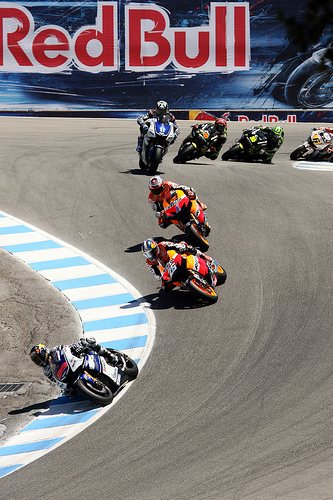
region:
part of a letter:
[207, 22, 226, 64]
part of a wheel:
[88, 388, 104, 403]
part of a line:
[58, 429, 94, 464]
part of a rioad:
[250, 391, 284, 432]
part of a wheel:
[85, 387, 115, 420]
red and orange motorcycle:
[157, 250, 226, 301]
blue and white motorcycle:
[50, 345, 133, 403]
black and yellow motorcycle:
[222, 130, 280, 165]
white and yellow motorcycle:
[290, 125, 331, 163]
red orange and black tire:
[189, 278, 219, 302]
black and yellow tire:
[27, 344, 43, 363]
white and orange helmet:
[147, 174, 158, 184]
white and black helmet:
[153, 97, 164, 105]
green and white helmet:
[269, 123, 277, 131]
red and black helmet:
[213, 116, 224, 124]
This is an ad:
[7, 31, 241, 124]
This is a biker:
[136, 228, 238, 296]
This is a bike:
[193, 253, 238, 348]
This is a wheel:
[71, 369, 132, 423]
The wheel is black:
[64, 364, 140, 437]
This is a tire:
[78, 394, 114, 406]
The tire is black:
[39, 378, 153, 426]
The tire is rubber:
[86, 381, 110, 417]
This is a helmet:
[133, 219, 172, 284]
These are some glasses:
[129, 250, 149, 258]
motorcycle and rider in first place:
[26, 331, 139, 402]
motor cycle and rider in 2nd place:
[129, 231, 227, 310]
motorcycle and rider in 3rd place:
[146, 172, 212, 249]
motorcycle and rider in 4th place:
[132, 99, 180, 171]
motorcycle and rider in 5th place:
[171, 115, 229, 165]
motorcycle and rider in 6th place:
[219, 125, 284, 164]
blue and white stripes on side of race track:
[0, 208, 156, 482]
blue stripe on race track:
[0, 238, 66, 253]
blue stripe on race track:
[51, 272, 118, 288]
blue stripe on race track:
[79, 312, 149, 329]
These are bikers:
[125, 152, 194, 314]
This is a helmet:
[145, 175, 174, 213]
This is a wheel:
[154, 272, 206, 331]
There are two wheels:
[34, 357, 187, 396]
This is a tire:
[76, 377, 92, 388]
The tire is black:
[81, 394, 113, 405]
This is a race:
[70, 113, 152, 434]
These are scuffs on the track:
[218, 177, 262, 339]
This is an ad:
[233, 99, 327, 189]